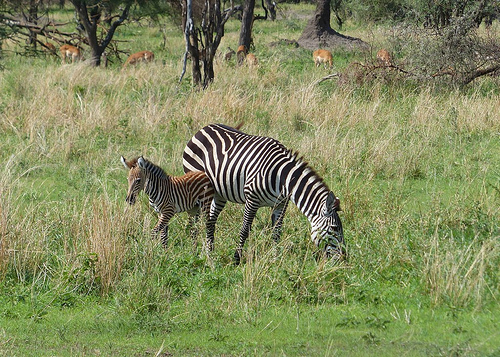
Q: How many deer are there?
A: Six.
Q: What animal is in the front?
A: Zebras.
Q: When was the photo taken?
A: Day time.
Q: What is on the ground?
A: Grass.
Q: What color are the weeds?
A: Tan.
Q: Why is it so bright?
A: Sunny.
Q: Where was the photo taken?
A: In a field.